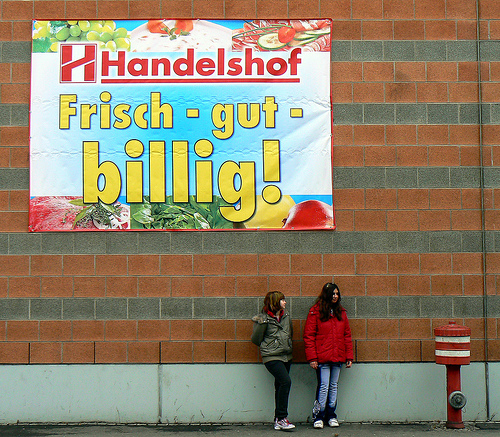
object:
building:
[0, 2, 499, 426]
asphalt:
[10, 418, 498, 437]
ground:
[208, 423, 237, 436]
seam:
[475, 0, 485, 371]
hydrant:
[433, 321, 470, 430]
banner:
[28, 15, 336, 232]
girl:
[249, 290, 296, 431]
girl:
[303, 281, 354, 428]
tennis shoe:
[275, 418, 295, 430]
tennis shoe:
[313, 419, 324, 428]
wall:
[337, 26, 354, 226]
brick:
[22, 0, 339, 22]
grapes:
[31, 20, 132, 53]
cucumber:
[232, 20, 331, 53]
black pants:
[264, 361, 291, 423]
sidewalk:
[267, 429, 298, 437]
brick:
[358, 20, 392, 37]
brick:
[395, 19, 424, 38]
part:
[381, 27, 391, 38]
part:
[271, 331, 282, 343]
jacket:
[251, 306, 294, 364]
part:
[310, 24, 324, 46]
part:
[477, 137, 484, 160]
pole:
[475, 80, 486, 197]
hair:
[317, 282, 343, 322]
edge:
[328, 20, 332, 58]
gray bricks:
[3, 232, 499, 257]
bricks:
[2, 256, 496, 276]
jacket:
[302, 299, 354, 364]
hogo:
[58, 41, 97, 84]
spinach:
[149, 195, 233, 230]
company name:
[100, 48, 302, 84]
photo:
[1, 1, 500, 437]